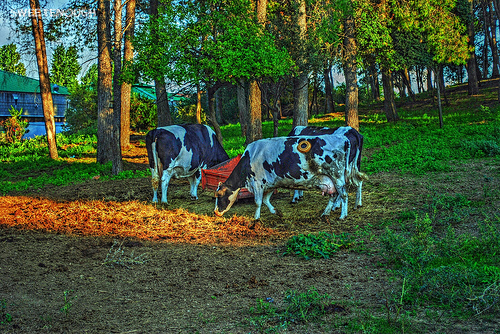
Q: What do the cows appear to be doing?
A: Eating.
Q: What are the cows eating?
A: Dried grass.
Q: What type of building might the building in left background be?
A: House.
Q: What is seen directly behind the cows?
A: Trees.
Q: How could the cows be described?
A: Black and white.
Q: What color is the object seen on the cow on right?
A: Yellow and black.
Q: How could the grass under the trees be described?
A: Green.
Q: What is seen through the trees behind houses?
A: Sky.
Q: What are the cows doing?
A: Eating.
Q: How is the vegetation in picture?
A: Dry.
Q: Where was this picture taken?
A: A farm.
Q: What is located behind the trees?
A: A building.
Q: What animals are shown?
A: Cows.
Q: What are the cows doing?
A: Eating.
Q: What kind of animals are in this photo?
A: Cows.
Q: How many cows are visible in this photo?
A: Three.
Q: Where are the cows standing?
A: Field.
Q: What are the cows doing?
A: Grazing.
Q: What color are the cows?
A: Black and white.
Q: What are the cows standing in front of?
A: Trees.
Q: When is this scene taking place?
A: Daytime.